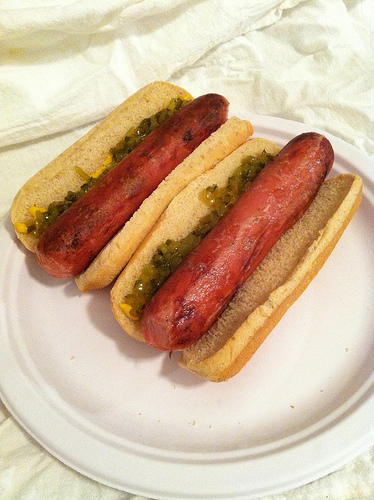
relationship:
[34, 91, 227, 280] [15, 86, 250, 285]
hotdog on bun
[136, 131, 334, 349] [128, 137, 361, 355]
hotdog on bun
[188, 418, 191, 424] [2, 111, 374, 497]
crumbs on paper plate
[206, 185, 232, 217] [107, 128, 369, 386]
relish on hot dog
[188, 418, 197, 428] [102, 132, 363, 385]
crumbs from bun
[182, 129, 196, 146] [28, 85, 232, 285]
char mark on hot dog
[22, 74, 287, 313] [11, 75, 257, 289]
relish on bun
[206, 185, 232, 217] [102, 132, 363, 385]
relish on bun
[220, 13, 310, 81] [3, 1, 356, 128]
white tablecloth on table